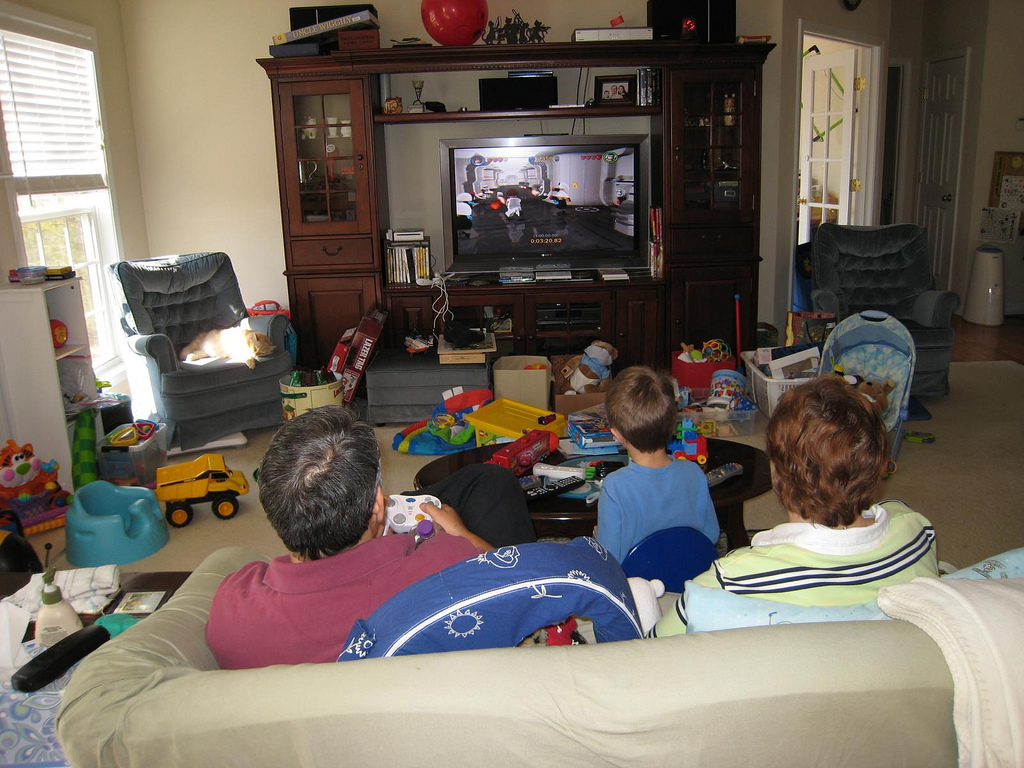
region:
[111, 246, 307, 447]
Dark grey recliner chair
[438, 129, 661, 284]
Flat screen television set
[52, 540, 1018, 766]
Cream colored couch with people on it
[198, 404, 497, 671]
Man holding game controller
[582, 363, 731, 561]
Child wearing a light blue shirt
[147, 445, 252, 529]
Yellow toy dump truck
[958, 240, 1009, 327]
White diaper disposal unit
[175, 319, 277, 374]
Cat sleeping on chair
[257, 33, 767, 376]
Wooden entertainment center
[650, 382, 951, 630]
Boy with multi-colored striped shirt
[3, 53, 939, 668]
Two adults and a child watching television in a messy room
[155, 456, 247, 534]
Toy truck on the floor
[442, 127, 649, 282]
Large flat-screen television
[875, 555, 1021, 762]
White blanket on the back of the sofa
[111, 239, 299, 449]
Gray chair in front of the window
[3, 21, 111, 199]
Blinds on the window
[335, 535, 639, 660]
Bloue pillow behind the man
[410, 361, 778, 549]
Boy sitting at a coffee table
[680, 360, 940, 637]
Woman wearing a striped sweater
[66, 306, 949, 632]
Toys all over the floor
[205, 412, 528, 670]
a man playing a video game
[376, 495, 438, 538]
a white video game controller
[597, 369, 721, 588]
a seated young boy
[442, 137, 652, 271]
a large screen flat TV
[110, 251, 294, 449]
a plush blue side chair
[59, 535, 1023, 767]
a light tan couch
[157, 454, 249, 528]
a bright yellow Tonka truck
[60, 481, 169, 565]
a blue child's seat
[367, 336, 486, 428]
a plush blue ottoman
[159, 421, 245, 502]
a truck on the floor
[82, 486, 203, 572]
a seat on the floor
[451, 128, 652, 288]
a tv on the stand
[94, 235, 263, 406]
a chair on the floor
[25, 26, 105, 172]
blinds no the window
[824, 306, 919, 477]
a bouncer on the floor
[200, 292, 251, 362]
a cat on the chair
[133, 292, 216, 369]
an orange cat on the chair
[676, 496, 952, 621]
The green and black striped shirt the person is wearing.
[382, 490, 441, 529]
The game controller in the man's hand.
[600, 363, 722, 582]
The child sitting in front of the adults.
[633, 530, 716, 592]
The chair the child is sitting on.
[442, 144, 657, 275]
The television in the middle of the entertainment center.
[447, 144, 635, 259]
The screen of the television.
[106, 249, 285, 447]
The gray recliner chair next to the window.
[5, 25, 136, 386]
The window behind the gray recliner.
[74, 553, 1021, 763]
The sofa the adults are sitting on.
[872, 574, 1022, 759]
The blanket draped over the sofa.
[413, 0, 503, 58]
nick knack on the wooden shelf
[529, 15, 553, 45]
nick knack on the wooden shelf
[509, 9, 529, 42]
nick knack on the wooden shelf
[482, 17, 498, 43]
nick knack on the wooden shelf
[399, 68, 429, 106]
nick knack on the wooden shelf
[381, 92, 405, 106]
nick knack on the wooden shelf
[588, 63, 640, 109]
nick knack on the wooden shelf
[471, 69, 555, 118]
nick knack on the wooden shelf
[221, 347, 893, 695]
A group of people playing video game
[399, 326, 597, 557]
What is was on the floor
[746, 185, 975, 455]
A gray chair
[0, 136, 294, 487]
A chair by the window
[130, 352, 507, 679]
In a with a red shirt on